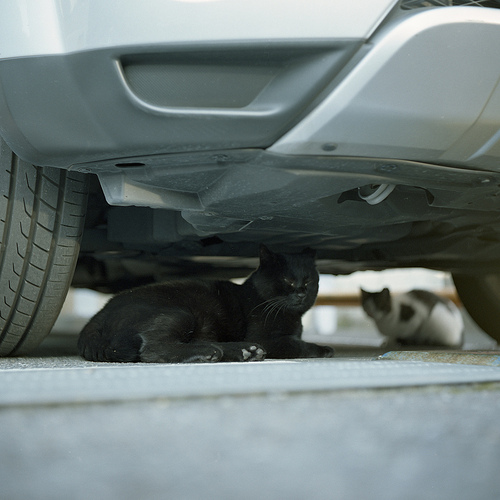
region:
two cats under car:
[127, 208, 489, 388]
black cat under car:
[77, 223, 317, 387]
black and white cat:
[338, 268, 488, 365]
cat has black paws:
[160, 328, 235, 378]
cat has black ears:
[245, 225, 317, 267]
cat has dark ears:
[352, 287, 397, 317]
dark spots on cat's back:
[372, 295, 449, 347]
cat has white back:
[432, 288, 464, 349]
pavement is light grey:
[147, 340, 408, 478]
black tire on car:
[0, 180, 87, 378]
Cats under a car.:
[72, 242, 480, 364]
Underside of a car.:
[80, 146, 498, 275]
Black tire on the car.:
[0, 138, 89, 353]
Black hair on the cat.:
[76, 241, 339, 368]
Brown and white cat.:
[357, 279, 479, 361]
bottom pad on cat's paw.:
[236, 342, 267, 363]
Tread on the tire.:
[0, 145, 85, 359]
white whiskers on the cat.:
[250, 289, 302, 327]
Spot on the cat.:
[394, 295, 418, 325]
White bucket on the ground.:
[308, 298, 343, 338]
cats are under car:
[112, 265, 476, 383]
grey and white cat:
[367, 281, 449, 365]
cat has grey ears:
[361, 285, 399, 295]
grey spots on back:
[378, 291, 450, 343]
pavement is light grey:
[134, 378, 345, 466]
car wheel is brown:
[0, 185, 97, 343]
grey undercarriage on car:
[121, 167, 438, 248]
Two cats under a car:
[17, 214, 499, 372]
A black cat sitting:
[80, 240, 330, 374]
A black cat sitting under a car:
[8, 237, 350, 417]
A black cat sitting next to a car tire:
[9, 226, 336, 396]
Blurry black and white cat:
[351, 279, 496, 365]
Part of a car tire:
[2, 238, 69, 353]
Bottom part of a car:
[27, 54, 499, 202]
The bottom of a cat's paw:
[230, 341, 268, 359]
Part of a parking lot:
[74, 366, 492, 476]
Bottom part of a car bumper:
[25, 19, 311, 119]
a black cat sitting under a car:
[75, 248, 342, 368]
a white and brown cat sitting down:
[350, 285, 464, 363]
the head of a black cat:
[251, 231, 325, 318]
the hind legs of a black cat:
[130, 316, 265, 383]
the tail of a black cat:
[72, 316, 127, 374]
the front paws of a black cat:
[255, 319, 320, 370]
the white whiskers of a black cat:
[250, 289, 294, 324]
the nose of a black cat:
[290, 283, 312, 308]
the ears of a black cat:
[247, 243, 285, 265]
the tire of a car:
[1, 139, 79, 347]